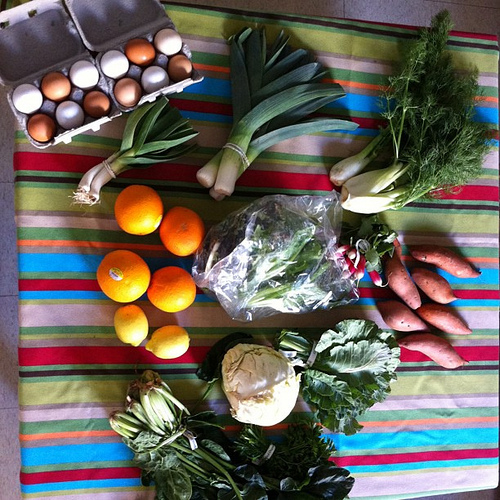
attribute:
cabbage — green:
[220, 340, 302, 426]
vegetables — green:
[70, 9, 500, 500]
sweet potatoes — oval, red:
[376, 229, 482, 372]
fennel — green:
[196, 26, 362, 201]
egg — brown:
[24, 112, 56, 144]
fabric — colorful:
[7, 4, 499, 496]